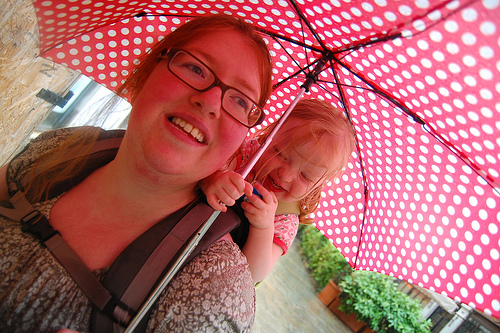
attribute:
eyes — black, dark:
[174, 52, 266, 121]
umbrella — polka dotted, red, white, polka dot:
[366, 20, 485, 219]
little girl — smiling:
[263, 99, 353, 204]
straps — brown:
[9, 184, 176, 292]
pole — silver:
[279, 89, 311, 109]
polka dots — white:
[435, 25, 479, 53]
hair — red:
[193, 12, 260, 32]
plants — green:
[346, 270, 405, 326]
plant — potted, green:
[367, 290, 415, 328]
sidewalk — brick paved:
[271, 297, 323, 326]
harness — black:
[24, 211, 64, 254]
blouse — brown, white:
[14, 272, 43, 304]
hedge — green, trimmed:
[305, 256, 333, 281]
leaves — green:
[379, 298, 398, 311]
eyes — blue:
[187, 63, 248, 110]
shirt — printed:
[20, 288, 79, 325]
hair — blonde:
[309, 108, 343, 139]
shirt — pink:
[276, 221, 300, 234]